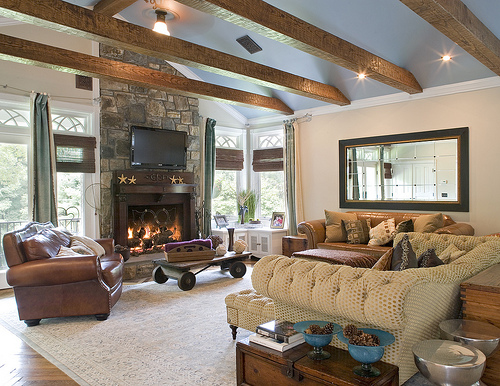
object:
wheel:
[229, 262, 250, 279]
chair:
[2, 220, 126, 330]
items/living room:
[335, 135, 470, 210]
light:
[442, 54, 452, 62]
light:
[358, 72, 365, 79]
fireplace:
[110, 169, 201, 256]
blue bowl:
[336, 326, 398, 365]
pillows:
[366, 216, 398, 246]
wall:
[294, 87, 497, 231]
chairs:
[298, 207, 476, 252]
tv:
[127, 125, 189, 171]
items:
[336, 322, 394, 377]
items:
[163, 234, 216, 262]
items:
[176, 175, 186, 185]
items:
[125, 175, 138, 185]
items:
[116, 172, 128, 183]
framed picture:
[268, 211, 285, 231]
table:
[245, 223, 287, 259]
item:
[151, 241, 251, 292]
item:
[292, 317, 341, 360]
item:
[410, 337, 490, 385]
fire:
[127, 221, 181, 252]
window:
[209, 123, 289, 226]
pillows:
[388, 234, 420, 270]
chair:
[218, 213, 500, 368]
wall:
[0, 64, 248, 132]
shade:
[250, 145, 288, 174]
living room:
[0, 0, 499, 385]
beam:
[1, 0, 500, 116]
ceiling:
[0, 1, 499, 121]